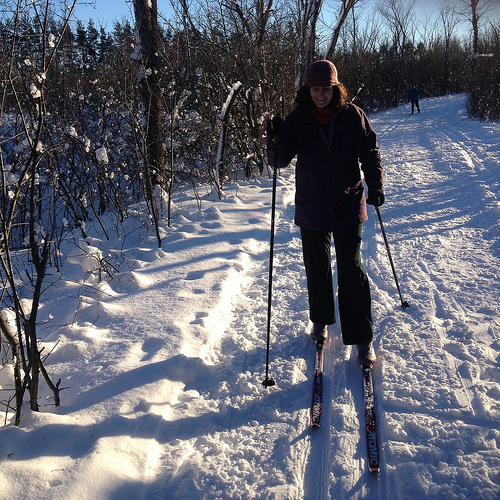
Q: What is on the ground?
A: Snow.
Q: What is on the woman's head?
A: A hat.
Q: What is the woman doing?
A: Skiing.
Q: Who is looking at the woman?
A: The photographer.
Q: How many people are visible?
A: Two.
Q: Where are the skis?
A: Under the woman's feet.